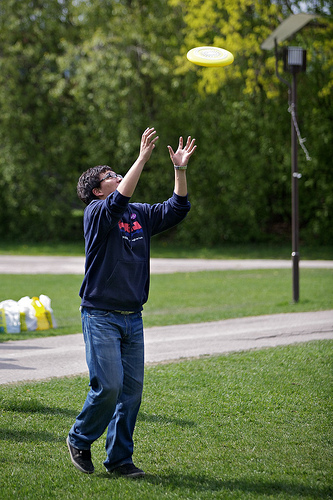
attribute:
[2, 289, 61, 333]
bags — plastic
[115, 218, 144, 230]
writing — pink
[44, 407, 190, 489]
shoes — black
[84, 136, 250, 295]
man — silver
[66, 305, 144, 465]
jeans — blue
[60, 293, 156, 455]
jeans — blue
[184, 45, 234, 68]
frisbee — yellow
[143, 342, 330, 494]
grass — short, green, yellow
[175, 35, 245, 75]
frisbee — yellow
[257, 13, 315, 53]
panel — solar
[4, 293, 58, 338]
bags — yellow, white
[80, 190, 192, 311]
sweatshirt — blue